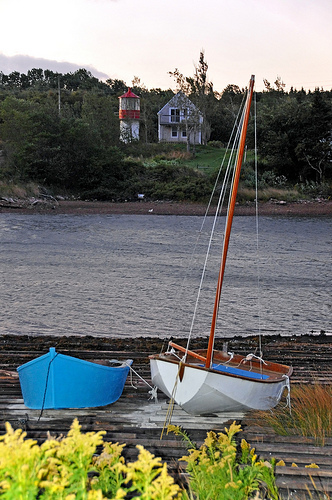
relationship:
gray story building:
[151, 93, 200, 149] [154, 85, 208, 143]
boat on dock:
[164, 76, 293, 408] [7, 324, 325, 442]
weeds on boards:
[253, 374, 330, 453] [4, 330, 318, 490]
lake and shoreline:
[0, 210, 332, 339] [27, 196, 332, 227]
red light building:
[113, 86, 142, 104] [154, 85, 208, 143]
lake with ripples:
[0, 210, 332, 339] [4, 211, 82, 238]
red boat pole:
[113, 86, 142, 104] [203, 71, 257, 372]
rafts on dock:
[15, 342, 137, 413] [7, 324, 325, 442]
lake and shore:
[0, 210, 332, 339] [4, 189, 331, 221]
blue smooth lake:
[5, 211, 325, 345] [0, 210, 332, 339]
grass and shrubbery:
[237, 180, 304, 207] [1, 93, 120, 195]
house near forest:
[117, 82, 144, 147] [5, 49, 328, 206]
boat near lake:
[164, 76, 293, 408] [0, 210, 332, 339]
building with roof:
[154, 85, 208, 143] [184, 88, 209, 118]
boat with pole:
[164, 76, 293, 408] [203, 71, 257, 372]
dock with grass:
[7, 324, 325, 442] [237, 180, 304, 207]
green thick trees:
[191, 49, 212, 76] [1, 51, 328, 198]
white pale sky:
[7, 4, 323, 93] [1, 2, 329, 100]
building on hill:
[154, 85, 208, 143] [7, 78, 327, 196]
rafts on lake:
[15, 342, 137, 413] [0, 210, 332, 339]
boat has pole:
[164, 76, 293, 408] [203, 71, 257, 372]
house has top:
[109, 74, 148, 147] [112, 82, 141, 99]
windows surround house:
[116, 99, 143, 108] [117, 82, 144, 147]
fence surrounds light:
[76, 105, 224, 145] [55, 70, 78, 119]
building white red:
[154, 85, 208, 143] [113, 86, 142, 104]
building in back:
[154, 85, 208, 143] [10, 64, 315, 197]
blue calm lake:
[5, 211, 325, 345] [0, 210, 328, 341]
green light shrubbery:
[191, 49, 212, 76] [1, 109, 125, 195]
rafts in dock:
[15, 342, 137, 413] [7, 324, 325, 442]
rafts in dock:
[15, 312, 289, 426] [7, 324, 325, 442]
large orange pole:
[201, 90, 259, 374] [200, 79, 258, 494]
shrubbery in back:
[1, 109, 125, 195] [10, 64, 315, 197]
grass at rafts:
[237, 180, 304, 207] [15, 312, 289, 426]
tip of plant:
[151, 419, 201, 454] [10, 419, 327, 499]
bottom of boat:
[151, 385, 236, 417] [164, 76, 293, 408]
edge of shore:
[1, 206, 330, 223] [4, 189, 331, 221]